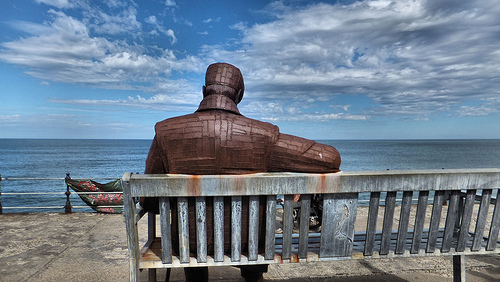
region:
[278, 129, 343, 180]
the arm of a statue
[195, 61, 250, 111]
the head of a statue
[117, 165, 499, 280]
a long metal bench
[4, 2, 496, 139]
a blue sky with clouds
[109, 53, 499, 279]
a statue sitting on a bench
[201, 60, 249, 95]
a statue wearing a hat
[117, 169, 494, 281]
a bench with rust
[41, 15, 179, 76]
this is the sky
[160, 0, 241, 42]
the sky is blue in color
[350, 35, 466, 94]
these are the clouds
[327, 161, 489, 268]
this is a bench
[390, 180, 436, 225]
the bench is metallic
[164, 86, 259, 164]
this is a jacket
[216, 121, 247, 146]
the jacket is brown in color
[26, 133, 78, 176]
this is a water body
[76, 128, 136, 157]
the water is calm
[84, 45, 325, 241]
statue on the bench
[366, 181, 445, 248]
back of the bench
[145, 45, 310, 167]
back of the statue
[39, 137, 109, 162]
water on the ocean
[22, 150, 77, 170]
the water is calm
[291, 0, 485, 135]
clouds in the sky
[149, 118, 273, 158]
the statue is brown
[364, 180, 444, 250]
the bench is wood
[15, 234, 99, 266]
the ground is concrete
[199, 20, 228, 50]
small clouds in sky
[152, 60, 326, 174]
statue on the bench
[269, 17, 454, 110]
clouds in the sky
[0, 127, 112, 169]
the body of water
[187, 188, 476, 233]
back of the bench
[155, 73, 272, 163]
back of the statue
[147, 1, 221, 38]
small clouds in sky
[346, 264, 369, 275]
shadow of the bench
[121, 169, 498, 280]
a metal bench on the concrete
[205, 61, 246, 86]
a brown hat on the man's head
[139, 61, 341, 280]
a man in brown sitting on a bench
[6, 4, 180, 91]
clouds in the blue sky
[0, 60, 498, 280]
a man sitting on a bench before the ocean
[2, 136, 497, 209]
water in the ocean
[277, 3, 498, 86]
dark and white clouds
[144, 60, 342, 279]
Statue is on the bench.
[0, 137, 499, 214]
Water in front of the statue.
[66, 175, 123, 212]
Cloth on the railing.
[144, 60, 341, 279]
Statue is wooden.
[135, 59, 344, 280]
brown wooden figure of a man sitting on a bench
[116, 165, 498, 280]
gray metal bench on the beach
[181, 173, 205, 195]
brown rust patch on the back of the bench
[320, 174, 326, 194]
brown rust patch on the back of the bench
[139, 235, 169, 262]
brown rust patch on the seat of the bench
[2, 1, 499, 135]
blue sky with white clouds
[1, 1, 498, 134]
white clouds in a blue sky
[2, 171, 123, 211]
silver metal fence with black post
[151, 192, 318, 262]
gray metal rails on back of bench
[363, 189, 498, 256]
gray metal rails on back of bench